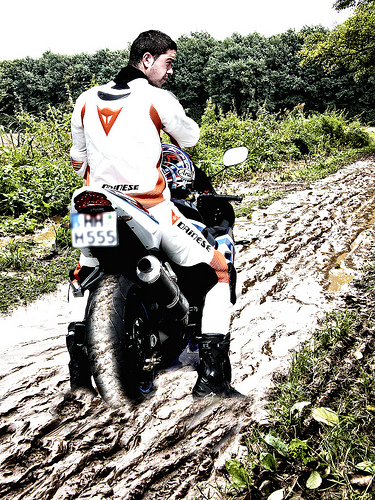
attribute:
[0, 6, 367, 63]
sky — open, wide, long, bright, white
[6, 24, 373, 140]
trees — green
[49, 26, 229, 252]
man — brown, close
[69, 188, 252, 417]
bike — close, black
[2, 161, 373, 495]
road — wet, muddy, close, brown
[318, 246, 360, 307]
water — muddy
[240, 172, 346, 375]
road — muddy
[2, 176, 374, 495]
ground — muddy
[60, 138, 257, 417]
bike — dirt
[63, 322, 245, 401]
boots — black